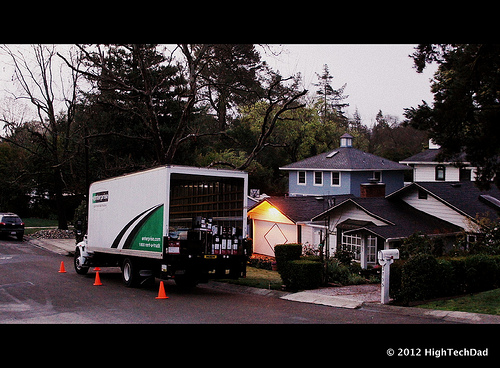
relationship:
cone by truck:
[56, 258, 68, 276] [72, 160, 251, 288]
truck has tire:
[72, 160, 251, 288] [67, 249, 90, 277]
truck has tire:
[72, 160, 251, 288] [117, 253, 143, 288]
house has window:
[276, 130, 413, 199] [371, 170, 386, 184]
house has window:
[276, 130, 413, 199] [328, 173, 345, 187]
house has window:
[276, 130, 413, 199] [312, 168, 326, 188]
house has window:
[276, 130, 413, 199] [297, 168, 307, 188]